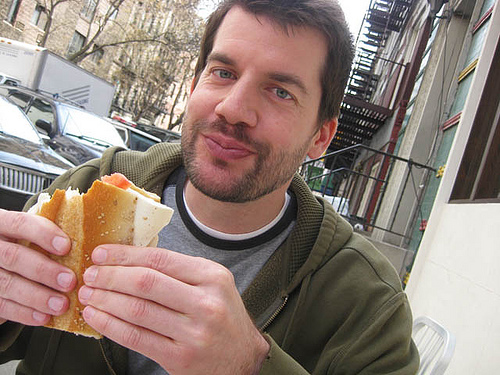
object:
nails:
[28, 225, 113, 339]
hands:
[76, 243, 263, 375]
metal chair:
[407, 313, 455, 373]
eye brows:
[206, 53, 235, 66]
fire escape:
[322, 0, 418, 173]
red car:
[113, 115, 137, 127]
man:
[0, 0, 422, 372]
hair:
[191, 0, 356, 136]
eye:
[269, 87, 295, 102]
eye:
[211, 70, 237, 81]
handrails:
[297, 143, 438, 239]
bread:
[14, 171, 174, 339]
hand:
[0, 206, 76, 327]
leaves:
[167, 22, 182, 37]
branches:
[139, 37, 173, 47]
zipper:
[259, 296, 290, 331]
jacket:
[0, 143, 421, 374]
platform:
[326, 92, 391, 178]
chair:
[406, 314, 455, 375]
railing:
[306, 141, 442, 250]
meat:
[102, 171, 132, 190]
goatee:
[180, 117, 312, 203]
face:
[180, 4, 330, 203]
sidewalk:
[362, 209, 412, 283]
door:
[399, 0, 491, 292]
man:
[16, 51, 430, 375]